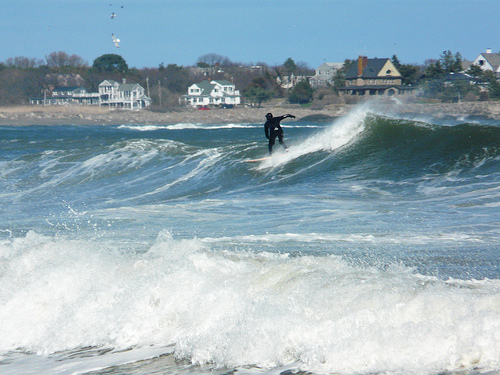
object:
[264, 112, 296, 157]
man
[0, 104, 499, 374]
ocean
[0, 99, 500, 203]
wave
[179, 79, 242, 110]
house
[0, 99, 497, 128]
beach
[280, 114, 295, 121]
arm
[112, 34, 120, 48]
bird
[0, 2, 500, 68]
sky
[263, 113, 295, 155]
wet suit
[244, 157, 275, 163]
surfboard